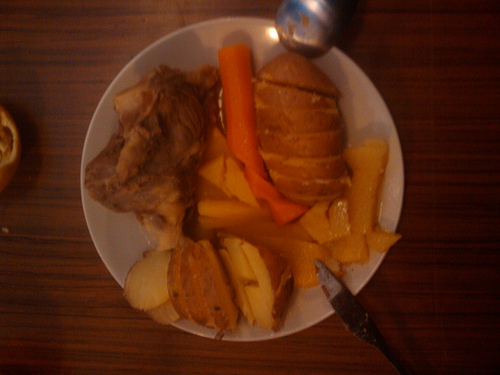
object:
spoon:
[275, 0, 338, 60]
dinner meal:
[83, 44, 402, 332]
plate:
[80, 17, 405, 342]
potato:
[299, 200, 335, 244]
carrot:
[217, 46, 309, 225]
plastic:
[79, 16, 405, 342]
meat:
[84, 61, 219, 250]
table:
[3, 2, 499, 374]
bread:
[253, 50, 350, 202]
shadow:
[367, 270, 432, 374]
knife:
[313, 258, 413, 374]